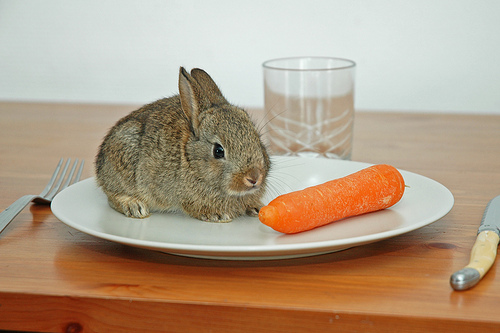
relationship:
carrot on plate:
[257, 163, 411, 234] [49, 154, 455, 261]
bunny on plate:
[97, 66, 272, 225] [49, 154, 455, 261]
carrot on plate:
[259, 163, 406, 233] [49, 154, 455, 261]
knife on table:
[452, 194, 498, 294] [1, 99, 497, 331]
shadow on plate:
[82, 200, 403, 251] [39, 139, 456, 268]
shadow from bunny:
[82, 200, 403, 251] [97, 66, 272, 225]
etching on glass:
[264, 111, 351, 160] [264, 55, 354, 160]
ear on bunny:
[176, 65, 206, 118] [97, 66, 272, 225]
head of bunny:
[180, 65, 270, 194] [92, 65, 273, 223]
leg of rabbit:
[108, 188, 150, 218] [91, 65, 271, 222]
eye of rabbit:
[212, 141, 225, 159] [91, 65, 271, 222]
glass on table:
[253, 54, 367, 186] [0, 75, 492, 325]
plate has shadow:
[49, 154, 455, 261] [66, 218, 451, 266]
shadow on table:
[66, 218, 451, 266] [1, 99, 497, 331]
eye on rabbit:
[200, 126, 231, 174] [91, 65, 271, 222]